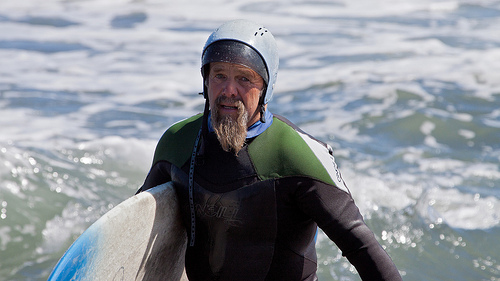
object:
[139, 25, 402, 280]
man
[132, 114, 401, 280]
wetsuit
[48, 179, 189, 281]
surfboard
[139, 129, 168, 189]
arm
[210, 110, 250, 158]
beard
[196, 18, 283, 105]
helmet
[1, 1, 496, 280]
sea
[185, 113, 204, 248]
strap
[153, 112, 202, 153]
shoulder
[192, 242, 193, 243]
down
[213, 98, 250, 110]
mustache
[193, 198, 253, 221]
logo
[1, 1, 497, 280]
water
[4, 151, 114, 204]
reflection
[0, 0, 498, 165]
white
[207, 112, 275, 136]
collar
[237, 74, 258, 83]
blue eyes